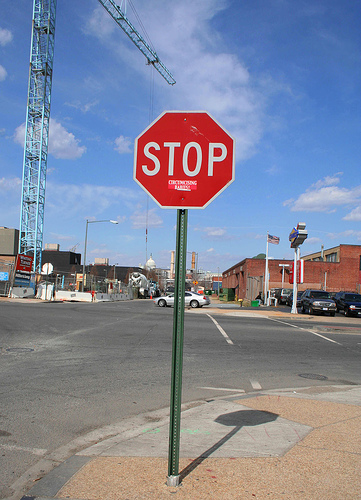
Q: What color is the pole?
A: Green.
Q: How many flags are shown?
A: 1.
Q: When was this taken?
A: Daytime.